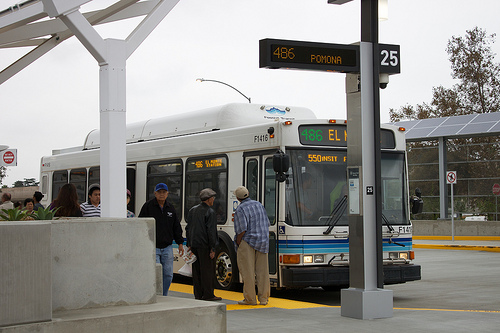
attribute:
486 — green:
[269, 39, 290, 63]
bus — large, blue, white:
[30, 137, 346, 278]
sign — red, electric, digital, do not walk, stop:
[442, 165, 458, 186]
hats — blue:
[197, 184, 259, 199]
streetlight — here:
[189, 74, 248, 102]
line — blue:
[179, 283, 257, 310]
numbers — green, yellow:
[380, 50, 397, 65]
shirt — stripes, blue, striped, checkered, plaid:
[231, 203, 270, 243]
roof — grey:
[18, 14, 122, 60]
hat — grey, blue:
[143, 181, 168, 193]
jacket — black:
[147, 210, 177, 249]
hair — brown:
[58, 181, 80, 222]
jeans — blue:
[148, 254, 169, 286]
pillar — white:
[97, 64, 135, 112]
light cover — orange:
[260, 130, 277, 144]